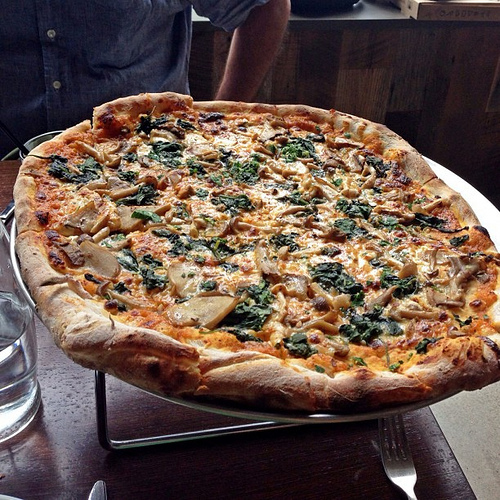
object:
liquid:
[0, 302, 39, 446]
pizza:
[8, 82, 500, 426]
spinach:
[309, 257, 365, 303]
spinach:
[338, 309, 383, 344]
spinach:
[222, 279, 276, 329]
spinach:
[285, 329, 316, 358]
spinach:
[378, 264, 421, 296]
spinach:
[335, 218, 373, 239]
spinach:
[193, 232, 237, 264]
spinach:
[74, 154, 103, 180]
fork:
[373, 408, 424, 500]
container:
[0, 209, 44, 453]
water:
[0, 292, 44, 449]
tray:
[6, 152, 500, 428]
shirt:
[0, 1, 265, 153]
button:
[43, 25, 57, 44]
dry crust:
[85, 89, 197, 121]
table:
[0, 157, 480, 499]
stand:
[88, 365, 304, 457]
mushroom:
[163, 291, 239, 338]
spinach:
[220, 151, 269, 190]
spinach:
[211, 187, 257, 215]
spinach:
[273, 188, 324, 217]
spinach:
[334, 198, 379, 225]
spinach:
[133, 254, 170, 292]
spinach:
[111, 186, 160, 210]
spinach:
[375, 214, 401, 236]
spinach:
[45, 155, 77, 183]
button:
[50, 79, 65, 94]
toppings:
[212, 131, 249, 149]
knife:
[81, 472, 113, 499]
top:
[87, 477, 109, 499]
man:
[0, 2, 296, 158]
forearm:
[199, 0, 293, 105]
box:
[393, 1, 499, 24]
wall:
[186, 18, 500, 210]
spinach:
[199, 279, 221, 291]